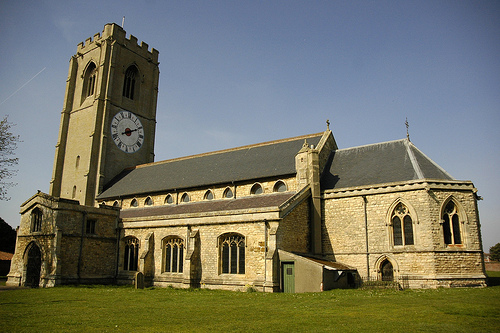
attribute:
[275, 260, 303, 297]
door — green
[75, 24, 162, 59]
roof — castle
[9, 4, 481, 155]
sky — blue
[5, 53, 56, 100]
trail — flying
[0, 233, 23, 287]
building — small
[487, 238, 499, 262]
tree — short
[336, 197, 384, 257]
thos — wall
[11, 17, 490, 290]
building — stone